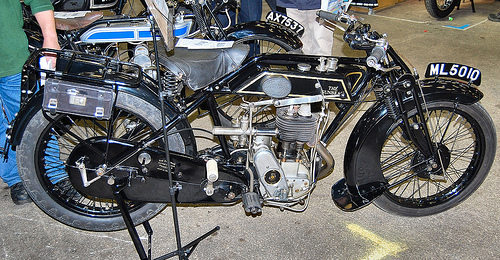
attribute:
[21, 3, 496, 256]
motorcycle — old, old fashioned, ready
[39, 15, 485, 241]
motorcycle — antique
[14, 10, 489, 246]
fashioned motorcyle — old fashioned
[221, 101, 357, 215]
engine in motorcycle — old